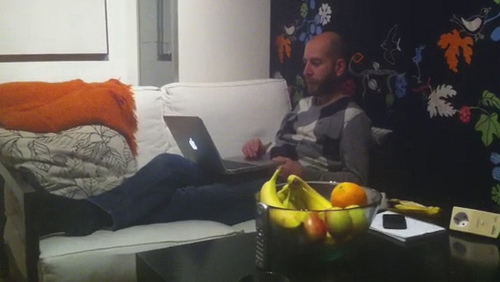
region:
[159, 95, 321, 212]
the laptop is silver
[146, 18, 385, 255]
the laptop is is on man's lap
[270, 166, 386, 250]
the fruits in the bowl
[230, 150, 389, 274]
the bowl on the table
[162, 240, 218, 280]
the table is black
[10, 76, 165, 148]
the blanket on the couch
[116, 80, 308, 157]
the couch is white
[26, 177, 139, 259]
the socks are black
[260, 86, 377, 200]
the shirt is gray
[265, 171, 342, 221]
the bananas are yellow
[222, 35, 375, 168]
this is a man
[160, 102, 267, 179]
the man is using a laptop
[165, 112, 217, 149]
the laptop is grey in color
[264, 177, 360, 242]
fruits are on the table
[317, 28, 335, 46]
the man is bald headed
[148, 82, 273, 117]
the sofa pillows are white in color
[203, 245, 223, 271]
the table is black in color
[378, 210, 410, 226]
a cellphone is on the table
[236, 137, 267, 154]
the mans hand is on the laptop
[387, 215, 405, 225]
the cell phone is black in color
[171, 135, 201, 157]
apple logo of the laptop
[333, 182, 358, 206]
part of an orange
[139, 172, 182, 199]
part of a jeans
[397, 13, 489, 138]
part of the wall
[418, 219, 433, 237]
part of a notebook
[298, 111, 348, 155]
part of a sweater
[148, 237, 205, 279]
part of a dark table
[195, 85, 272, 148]
part of a white cushion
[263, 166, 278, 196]
tip of a banana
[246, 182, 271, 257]
part of a cellphone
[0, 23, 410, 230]
man sitting on couch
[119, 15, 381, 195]
lap top on mans lap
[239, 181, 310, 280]
mobile phone on table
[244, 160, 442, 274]
fruits in bowl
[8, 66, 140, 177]
orange throw on couch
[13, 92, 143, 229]
pillow on couch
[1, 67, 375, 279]
white couch with wooden arm rest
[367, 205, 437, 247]
cellphone on papers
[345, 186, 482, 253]
papers on table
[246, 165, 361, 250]
bananas in fruit bowl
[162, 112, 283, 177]
silver apple laptop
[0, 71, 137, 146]
orange blanket with fray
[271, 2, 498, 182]
colorful floral design on a wall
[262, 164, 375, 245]
basket of various fruits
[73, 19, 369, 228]
bald man on a couch using his laptop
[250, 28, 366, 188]
man wearing a sweater with an argyle design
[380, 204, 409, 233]
black cellphone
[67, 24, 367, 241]
man sitting on a white couch with his legs crossed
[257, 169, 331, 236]
bunch of bananas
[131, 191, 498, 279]
black coffee table with various items on it